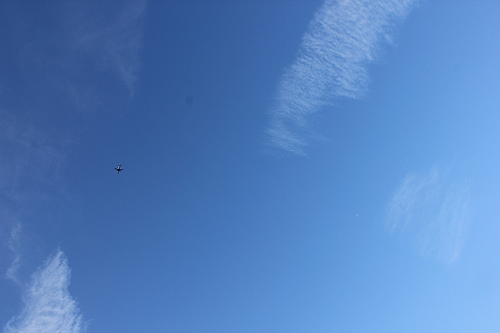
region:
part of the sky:
[175, 142, 231, 222]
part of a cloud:
[24, 250, 69, 300]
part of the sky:
[151, 177, 202, 250]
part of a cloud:
[286, 84, 337, 150]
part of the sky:
[205, 167, 254, 237]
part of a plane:
[83, 146, 133, 186]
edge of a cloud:
[48, 251, 84, 297]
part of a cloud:
[306, 102, 320, 120]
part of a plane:
[87, 157, 119, 171]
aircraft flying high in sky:
[93, 154, 150, 196]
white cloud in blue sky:
[252, 2, 377, 154]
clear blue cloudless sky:
[131, 197, 291, 281]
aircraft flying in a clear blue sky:
[86, 147, 172, 213]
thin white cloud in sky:
[0, 234, 100, 330]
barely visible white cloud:
[26, 0, 169, 122]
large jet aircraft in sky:
[69, 139, 174, 199]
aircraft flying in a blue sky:
[7, 130, 189, 217]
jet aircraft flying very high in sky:
[109, 161, 128, 176]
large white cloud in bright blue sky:
[266, 0, 438, 166]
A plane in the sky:
[112, 157, 122, 172]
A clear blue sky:
[5, 0, 490, 325]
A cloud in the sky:
[5, 215, 100, 325]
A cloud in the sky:
[380, 155, 490, 270]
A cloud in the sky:
[250, 0, 425, 160]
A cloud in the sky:
[15, 10, 160, 140]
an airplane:
[100, 155, 125, 175]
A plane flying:
[110, 155, 121, 175]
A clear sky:
[0, 1, 495, 329]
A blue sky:
[2, 1, 499, 331]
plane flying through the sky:
[109, 160, 130, 178]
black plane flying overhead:
[105, 162, 136, 174]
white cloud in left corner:
[13, 245, 93, 330]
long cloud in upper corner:
[262, 7, 423, 147]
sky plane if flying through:
[10, 7, 480, 314]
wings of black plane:
[113, 167, 126, 174]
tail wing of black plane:
[114, 163, 124, 166]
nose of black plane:
[118, 167, 125, 175]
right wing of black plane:
[120, 168, 127, 175]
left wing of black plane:
[114, 165, 117, 171]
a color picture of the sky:
[1, 2, 498, 329]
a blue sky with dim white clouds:
[1, 2, 498, 331]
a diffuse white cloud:
[254, 0, 426, 162]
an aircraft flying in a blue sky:
[103, 155, 129, 185]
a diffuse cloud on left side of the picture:
[5, 225, 95, 330]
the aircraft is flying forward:
[103, 156, 133, 184]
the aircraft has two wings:
[106, 157, 130, 179]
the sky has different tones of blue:
[2, 0, 497, 332]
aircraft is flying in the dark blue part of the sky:
[3, 5, 220, 228]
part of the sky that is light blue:
[236, 105, 494, 331]